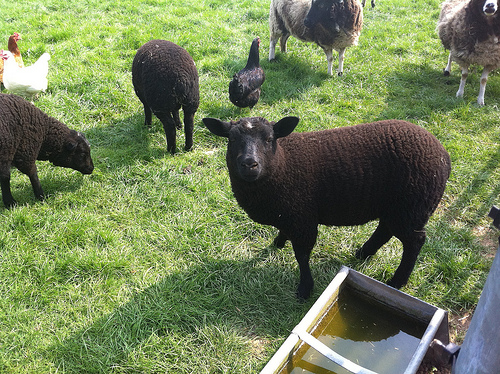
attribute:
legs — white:
[441, 47, 498, 117]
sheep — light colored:
[277, 1, 499, 85]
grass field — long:
[4, 6, 497, 371]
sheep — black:
[200, 112, 456, 292]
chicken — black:
[229, 33, 264, 111]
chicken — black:
[226, 36, 268, 115]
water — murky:
[312, 280, 428, 372]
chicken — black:
[231, 36, 266, 105]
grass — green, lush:
[1, 2, 499, 372]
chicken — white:
[1, 50, 49, 105]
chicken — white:
[0, 51, 56, 102]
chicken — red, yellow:
[3, 30, 28, 87]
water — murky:
[336, 313, 398, 350]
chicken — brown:
[1, 50, 47, 88]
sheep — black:
[0, 81, 101, 221]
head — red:
[8, 30, 22, 51]